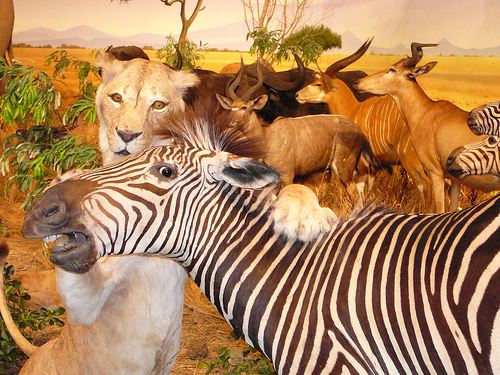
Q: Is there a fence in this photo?
A: No, there are no fences.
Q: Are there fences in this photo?
A: No, there are no fences.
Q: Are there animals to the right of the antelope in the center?
A: Yes, there is an animal to the right of the antelope.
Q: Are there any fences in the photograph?
A: No, there are no fences.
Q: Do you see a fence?
A: No, there are no fences.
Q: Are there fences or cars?
A: No, there are no fences or cars.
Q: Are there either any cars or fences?
A: No, there are no fences or cars.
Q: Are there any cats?
A: Yes, there is a cat.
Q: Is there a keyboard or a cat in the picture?
A: Yes, there is a cat.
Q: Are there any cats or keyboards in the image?
A: Yes, there is a cat.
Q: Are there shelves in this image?
A: No, there are no shelves.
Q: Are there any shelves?
A: No, there are no shelves.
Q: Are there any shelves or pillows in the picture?
A: No, there are no shelves or pillows.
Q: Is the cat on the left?
A: Yes, the cat is on the left of the image.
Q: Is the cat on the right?
A: No, the cat is on the left of the image.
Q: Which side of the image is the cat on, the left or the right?
A: The cat is on the left of the image.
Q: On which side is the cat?
A: The cat is on the left of the image.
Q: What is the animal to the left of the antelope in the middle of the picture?
A: The animal is a cat.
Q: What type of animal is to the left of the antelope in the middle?
A: The animal is a cat.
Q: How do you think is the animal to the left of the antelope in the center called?
A: The animal is a cat.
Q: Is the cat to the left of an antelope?
A: Yes, the cat is to the left of an antelope.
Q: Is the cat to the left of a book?
A: No, the cat is to the left of an antelope.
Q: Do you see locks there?
A: No, there are no locks.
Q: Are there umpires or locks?
A: No, there are no locks or umpires.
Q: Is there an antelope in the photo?
A: Yes, there is an antelope.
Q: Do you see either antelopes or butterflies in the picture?
A: Yes, there is an antelope.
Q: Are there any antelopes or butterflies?
A: Yes, there is an antelope.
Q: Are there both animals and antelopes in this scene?
A: Yes, there are both an antelope and an animal.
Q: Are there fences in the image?
A: No, there are no fences.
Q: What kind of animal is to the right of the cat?
A: The animal is an antelope.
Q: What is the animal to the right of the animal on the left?
A: The animal is an antelope.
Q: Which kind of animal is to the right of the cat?
A: The animal is an antelope.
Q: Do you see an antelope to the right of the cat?
A: Yes, there is an antelope to the right of the cat.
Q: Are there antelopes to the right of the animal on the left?
A: Yes, there is an antelope to the right of the cat.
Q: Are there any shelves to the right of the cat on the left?
A: No, there is an antelope to the right of the cat.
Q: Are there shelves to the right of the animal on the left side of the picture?
A: No, there is an antelope to the right of the cat.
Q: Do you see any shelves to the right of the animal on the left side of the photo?
A: No, there is an antelope to the right of the cat.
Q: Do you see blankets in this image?
A: No, there are no blankets.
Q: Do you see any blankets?
A: No, there are no blankets.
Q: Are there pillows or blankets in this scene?
A: No, there are no blankets or pillows.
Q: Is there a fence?
A: No, there are no fences.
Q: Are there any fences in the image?
A: No, there are no fences.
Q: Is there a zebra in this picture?
A: Yes, there is a zebra.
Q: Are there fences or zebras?
A: Yes, there is a zebra.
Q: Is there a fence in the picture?
A: No, there are no fences.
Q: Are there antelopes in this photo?
A: Yes, there is an antelope.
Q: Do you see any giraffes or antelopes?
A: Yes, there is an antelope.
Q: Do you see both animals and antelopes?
A: Yes, there are both an antelope and an animal.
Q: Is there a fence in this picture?
A: No, there are no fences.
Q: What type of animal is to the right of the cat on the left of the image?
A: The animal is an antelope.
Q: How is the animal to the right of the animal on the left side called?
A: The animal is an antelope.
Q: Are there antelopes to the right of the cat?
A: Yes, there is an antelope to the right of the cat.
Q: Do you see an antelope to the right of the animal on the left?
A: Yes, there is an antelope to the right of the cat.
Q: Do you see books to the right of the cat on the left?
A: No, there is an antelope to the right of the cat.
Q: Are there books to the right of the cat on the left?
A: No, there is an antelope to the right of the cat.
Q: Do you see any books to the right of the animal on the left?
A: No, there is an antelope to the right of the cat.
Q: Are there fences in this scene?
A: No, there are no fences.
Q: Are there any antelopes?
A: Yes, there is an antelope.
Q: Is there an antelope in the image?
A: Yes, there is an antelope.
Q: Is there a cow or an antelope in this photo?
A: Yes, there is an antelope.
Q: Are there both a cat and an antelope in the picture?
A: Yes, there are both an antelope and a cat.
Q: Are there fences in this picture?
A: No, there are no fences.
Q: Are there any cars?
A: No, there are no cars.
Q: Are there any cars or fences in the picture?
A: No, there are no cars or fences.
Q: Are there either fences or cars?
A: No, there are no cars or fences.